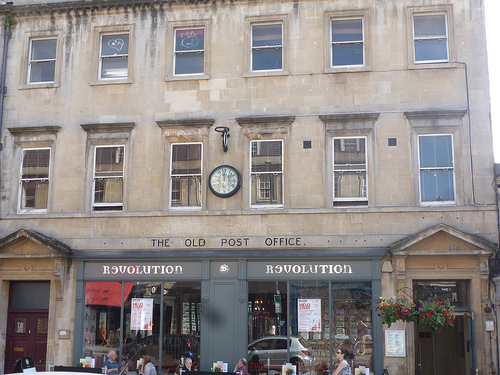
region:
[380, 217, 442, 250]
edge of a roof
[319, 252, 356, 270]
part of a graphic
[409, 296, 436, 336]
part of a plant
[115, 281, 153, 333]
part of a glass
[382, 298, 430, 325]
part of a plant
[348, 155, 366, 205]
part of a door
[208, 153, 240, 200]
part of a clock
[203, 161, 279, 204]
clock on the building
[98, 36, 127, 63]
a heart drawn on the window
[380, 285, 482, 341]
two hanging flowers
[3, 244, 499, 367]
two entries to the building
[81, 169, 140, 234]
the window is open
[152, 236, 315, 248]
THE OLD POST OFFICE is the building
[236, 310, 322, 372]
car reflection in the window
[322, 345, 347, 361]
woman wearing sunglasses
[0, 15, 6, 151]
pipe attached to building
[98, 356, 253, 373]
people sitting at tables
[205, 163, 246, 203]
this is a clock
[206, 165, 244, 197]
the clock is big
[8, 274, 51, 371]
this is a door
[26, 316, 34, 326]
the door is brown in color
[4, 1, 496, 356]
this is a building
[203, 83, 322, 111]
the building is cream in color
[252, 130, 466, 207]
these are some windows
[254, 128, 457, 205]
the windows are closed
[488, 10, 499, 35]
this is the sky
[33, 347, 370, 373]
these are some people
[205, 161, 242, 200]
black and white clock on the side of the building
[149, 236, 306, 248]
black lettering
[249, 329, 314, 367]
reflecton of a car in the window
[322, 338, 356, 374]
woman walking down the street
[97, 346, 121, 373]
old man sitting down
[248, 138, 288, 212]
white window pane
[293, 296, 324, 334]
red and white sign posted in the window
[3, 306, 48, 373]
maroon door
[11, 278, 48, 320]
frosted glass above the door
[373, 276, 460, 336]
potted plants hanging off the wall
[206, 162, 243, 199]
clock on building face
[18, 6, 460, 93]
windows on building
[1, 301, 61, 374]
door to large building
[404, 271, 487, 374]
door to large building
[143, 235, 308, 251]
sign on building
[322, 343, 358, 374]
woman wearing sunglasses sitting at a table outside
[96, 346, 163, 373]
people sitting at a table outside of a large building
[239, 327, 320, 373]
silver car driving down street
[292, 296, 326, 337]
sign on front window of building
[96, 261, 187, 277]
sign on store front